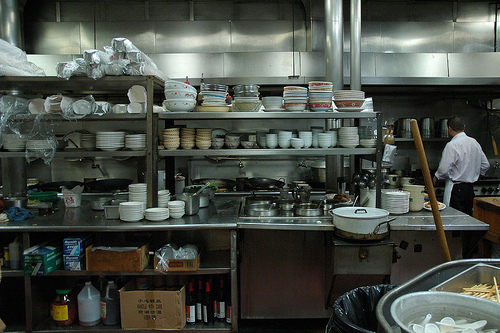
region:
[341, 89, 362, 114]
round bowls on top of plate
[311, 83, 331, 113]
stack of round bowls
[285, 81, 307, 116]
short stack of round bowls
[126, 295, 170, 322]
black lettering on box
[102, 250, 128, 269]
front of brown box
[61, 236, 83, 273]
double box of wraps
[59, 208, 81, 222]
top of silver counter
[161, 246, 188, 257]
box of plastic cups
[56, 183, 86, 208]
empty chinese food cartoon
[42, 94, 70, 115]
empty chinese cartons in plastic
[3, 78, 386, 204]
a large assortment of bowls and plates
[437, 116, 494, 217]
a man with an apron on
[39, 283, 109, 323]
jars and bottles on the bottom of a shelf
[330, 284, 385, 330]
a trashcan with a black garbage bag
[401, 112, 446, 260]
a handle to a mop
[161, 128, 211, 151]
a set of yellow bowls on a shelf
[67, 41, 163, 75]
a bag of plastic cups on top of a shelf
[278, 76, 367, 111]
a group of red and white bowls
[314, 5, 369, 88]
a metal pole in the center of a room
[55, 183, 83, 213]
a chinese take out box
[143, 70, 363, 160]
many dishes in photo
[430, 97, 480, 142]
head of the man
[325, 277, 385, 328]
black trash bag in photo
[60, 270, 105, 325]
bottle in the photo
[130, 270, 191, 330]
box under the shelf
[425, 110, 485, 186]
man with back towards camera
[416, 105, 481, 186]
man wearing white and black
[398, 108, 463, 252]
brown pole in photo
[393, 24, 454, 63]
light hitting the wall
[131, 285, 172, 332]
writing on the box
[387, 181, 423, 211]
a set of plates on a metal countertop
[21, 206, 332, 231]
a large metal work surface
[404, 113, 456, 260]
a broom handle leaning over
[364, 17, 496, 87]
the ducts of air work in a kitchen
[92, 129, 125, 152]
a small stack of white plates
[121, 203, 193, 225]
an assortment of bowls on a countertop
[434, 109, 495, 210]
a waiter in the back of a kitchen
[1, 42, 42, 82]
a large plastic bag on top of a shelf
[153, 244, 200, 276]
a box containing plasticwear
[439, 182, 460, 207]
a white apron being worn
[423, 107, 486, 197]
person in the kitchen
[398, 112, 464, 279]
pole in the kitchen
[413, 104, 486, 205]
man in white outfit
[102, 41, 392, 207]
dishes in the photo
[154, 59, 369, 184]
many dishes in the photo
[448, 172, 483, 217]
pants on the man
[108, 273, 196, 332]
box on the shelf